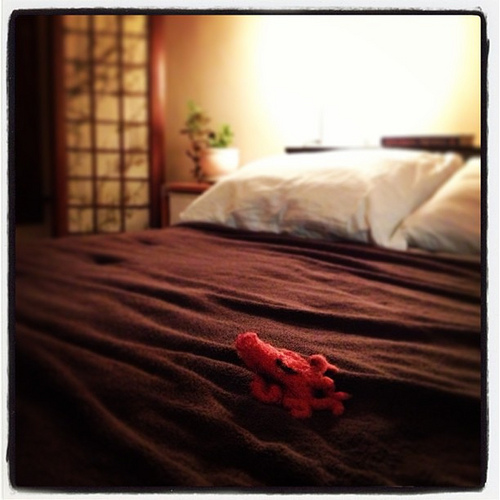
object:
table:
[162, 183, 215, 229]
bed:
[7, 134, 487, 495]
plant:
[180, 102, 241, 186]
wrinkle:
[352, 192, 392, 260]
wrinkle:
[163, 393, 295, 465]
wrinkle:
[212, 282, 466, 344]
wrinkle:
[34, 307, 174, 383]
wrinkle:
[38, 352, 171, 461]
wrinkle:
[362, 352, 479, 404]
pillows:
[180, 148, 482, 257]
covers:
[11, 220, 483, 492]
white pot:
[199, 147, 239, 181]